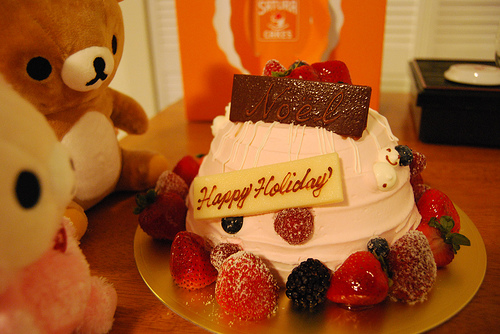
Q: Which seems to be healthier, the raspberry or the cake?
A: The raspberry is healthier than the cake.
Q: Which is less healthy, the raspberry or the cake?
A: The cake is less healthy than the raspberry.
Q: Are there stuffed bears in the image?
A: Yes, there is a stuffed bear.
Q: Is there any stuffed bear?
A: Yes, there is a stuffed bear.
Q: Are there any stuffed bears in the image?
A: Yes, there is a stuffed bear.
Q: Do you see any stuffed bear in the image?
A: Yes, there is a stuffed bear.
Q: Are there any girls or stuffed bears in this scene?
A: Yes, there is a stuffed bear.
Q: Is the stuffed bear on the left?
A: Yes, the stuffed bear is on the left of the image.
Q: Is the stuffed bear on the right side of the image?
A: No, the stuffed bear is on the left of the image.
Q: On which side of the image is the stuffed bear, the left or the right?
A: The stuffed bear is on the left of the image.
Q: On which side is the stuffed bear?
A: The stuffed bear is on the left of the image.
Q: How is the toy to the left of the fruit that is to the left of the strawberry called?
A: The toy is a stuffed bear.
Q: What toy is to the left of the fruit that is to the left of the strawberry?
A: The toy is a stuffed bear.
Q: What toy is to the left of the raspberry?
A: The toy is a stuffed bear.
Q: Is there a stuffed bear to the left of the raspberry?
A: Yes, there is a stuffed bear to the left of the raspberry.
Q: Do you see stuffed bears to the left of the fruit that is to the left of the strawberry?
A: Yes, there is a stuffed bear to the left of the raspberry.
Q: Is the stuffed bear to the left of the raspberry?
A: Yes, the stuffed bear is to the left of the raspberry.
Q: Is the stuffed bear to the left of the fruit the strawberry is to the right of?
A: Yes, the stuffed bear is to the left of the raspberry.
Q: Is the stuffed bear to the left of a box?
A: Yes, the stuffed bear is to the left of a box.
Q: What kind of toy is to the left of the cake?
A: The toy is a stuffed bear.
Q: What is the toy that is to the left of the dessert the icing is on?
A: The toy is a stuffed bear.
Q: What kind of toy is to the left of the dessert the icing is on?
A: The toy is a stuffed bear.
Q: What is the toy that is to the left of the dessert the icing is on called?
A: The toy is a stuffed bear.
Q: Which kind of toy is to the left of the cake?
A: The toy is a stuffed bear.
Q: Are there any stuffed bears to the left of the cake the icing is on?
A: Yes, there is a stuffed bear to the left of the cake.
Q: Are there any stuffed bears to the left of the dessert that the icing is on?
A: Yes, there is a stuffed bear to the left of the cake.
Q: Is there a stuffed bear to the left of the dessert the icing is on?
A: Yes, there is a stuffed bear to the left of the cake.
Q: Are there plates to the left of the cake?
A: No, there is a stuffed bear to the left of the cake.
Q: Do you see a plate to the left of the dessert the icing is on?
A: No, there is a stuffed bear to the left of the cake.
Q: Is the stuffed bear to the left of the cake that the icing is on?
A: Yes, the stuffed bear is to the left of the cake.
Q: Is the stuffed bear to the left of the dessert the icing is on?
A: Yes, the stuffed bear is to the left of the cake.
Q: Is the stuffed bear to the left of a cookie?
A: No, the stuffed bear is to the left of the cake.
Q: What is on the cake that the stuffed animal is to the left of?
A: The icing is on the cake.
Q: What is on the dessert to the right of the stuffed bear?
A: The icing is on the cake.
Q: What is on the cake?
A: The icing is on the cake.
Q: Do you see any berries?
A: Yes, there are berries.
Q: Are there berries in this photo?
A: Yes, there are berries.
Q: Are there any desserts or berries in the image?
A: Yes, there are berries.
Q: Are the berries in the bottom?
A: Yes, the berries are in the bottom of the image.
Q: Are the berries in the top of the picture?
A: No, the berries are in the bottom of the image.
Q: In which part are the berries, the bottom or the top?
A: The berries are in the bottom of the image.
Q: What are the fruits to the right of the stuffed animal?
A: The fruits are berries.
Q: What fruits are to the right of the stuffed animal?
A: The fruits are berries.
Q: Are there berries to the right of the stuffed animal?
A: Yes, there are berries to the right of the stuffed animal.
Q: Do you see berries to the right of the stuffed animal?
A: Yes, there are berries to the right of the stuffed animal.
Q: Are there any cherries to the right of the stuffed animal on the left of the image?
A: No, there are berries to the right of the stuffed animal.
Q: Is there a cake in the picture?
A: Yes, there is a cake.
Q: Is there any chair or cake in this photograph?
A: Yes, there is a cake.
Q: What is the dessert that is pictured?
A: The dessert is a cake.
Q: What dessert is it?
A: The dessert is a cake.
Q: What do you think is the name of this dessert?
A: This is a cake.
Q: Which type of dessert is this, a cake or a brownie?
A: This is a cake.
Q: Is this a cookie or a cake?
A: This is a cake.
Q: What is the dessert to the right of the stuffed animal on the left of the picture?
A: The dessert is a cake.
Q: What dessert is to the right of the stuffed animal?
A: The dessert is a cake.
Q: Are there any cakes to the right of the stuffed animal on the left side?
A: Yes, there is a cake to the right of the stuffed animal.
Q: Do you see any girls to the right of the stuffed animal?
A: No, there is a cake to the right of the stuffed animal.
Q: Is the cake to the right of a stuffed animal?
A: Yes, the cake is to the right of a stuffed animal.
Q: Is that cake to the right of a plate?
A: No, the cake is to the right of a stuffed animal.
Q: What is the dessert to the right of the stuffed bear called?
A: The dessert is a cake.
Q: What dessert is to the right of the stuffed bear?
A: The dessert is a cake.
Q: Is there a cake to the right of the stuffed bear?
A: Yes, there is a cake to the right of the stuffed bear.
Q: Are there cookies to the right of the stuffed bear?
A: No, there is a cake to the right of the stuffed bear.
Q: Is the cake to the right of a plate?
A: No, the cake is to the right of the stuffed bear.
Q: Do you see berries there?
A: Yes, there are berries.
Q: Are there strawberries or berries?
A: Yes, there are berries.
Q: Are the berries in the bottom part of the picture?
A: Yes, the berries are in the bottom of the image.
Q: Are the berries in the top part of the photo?
A: No, the berries are in the bottom of the image.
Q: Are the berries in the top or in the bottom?
A: The berries are in the bottom of the image.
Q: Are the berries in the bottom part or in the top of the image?
A: The berries are in the bottom of the image.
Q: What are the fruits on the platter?
A: The fruits are berries.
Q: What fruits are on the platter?
A: The fruits are berries.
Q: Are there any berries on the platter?
A: Yes, there are berries on the platter.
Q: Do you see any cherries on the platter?
A: No, there are berries on the platter.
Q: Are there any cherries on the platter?
A: No, there are berries on the platter.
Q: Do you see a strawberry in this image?
A: Yes, there is a strawberry.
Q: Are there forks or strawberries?
A: Yes, there is a strawberry.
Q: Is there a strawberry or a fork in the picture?
A: Yes, there is a strawberry.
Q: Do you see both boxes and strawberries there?
A: Yes, there are both a strawberry and a box.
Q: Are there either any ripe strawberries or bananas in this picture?
A: Yes, there is a ripe strawberry.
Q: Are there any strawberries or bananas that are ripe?
A: Yes, the strawberry is ripe.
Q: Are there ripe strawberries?
A: Yes, there is a ripe strawberry.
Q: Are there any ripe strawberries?
A: Yes, there is a ripe strawberry.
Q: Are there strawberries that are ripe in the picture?
A: Yes, there is a ripe strawberry.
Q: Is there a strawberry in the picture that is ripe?
A: Yes, there is a strawberry that is ripe.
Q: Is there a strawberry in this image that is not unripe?
A: Yes, there is an ripe strawberry.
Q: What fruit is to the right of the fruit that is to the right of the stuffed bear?
A: The fruit is a strawberry.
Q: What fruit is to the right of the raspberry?
A: The fruit is a strawberry.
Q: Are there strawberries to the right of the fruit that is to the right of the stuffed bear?
A: Yes, there is a strawberry to the right of the raspberry.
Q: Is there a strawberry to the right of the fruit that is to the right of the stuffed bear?
A: Yes, there is a strawberry to the right of the raspberry.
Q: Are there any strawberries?
A: Yes, there is a strawberry.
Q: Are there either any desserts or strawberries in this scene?
A: Yes, there is a strawberry.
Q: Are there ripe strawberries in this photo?
A: Yes, there is a ripe strawberry.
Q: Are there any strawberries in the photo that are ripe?
A: Yes, there is a strawberry that is ripe.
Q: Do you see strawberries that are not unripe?
A: Yes, there is an ripe strawberry.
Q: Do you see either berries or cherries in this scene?
A: Yes, there are berries.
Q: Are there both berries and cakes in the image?
A: Yes, there are both berries and a cake.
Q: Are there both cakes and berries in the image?
A: Yes, there are both berries and a cake.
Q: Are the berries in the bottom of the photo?
A: Yes, the berries are in the bottom of the image.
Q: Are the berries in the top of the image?
A: No, the berries are in the bottom of the image.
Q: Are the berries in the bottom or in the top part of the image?
A: The berries are in the bottom of the image.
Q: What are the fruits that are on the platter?
A: The fruits are berries.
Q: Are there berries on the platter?
A: Yes, there are berries on the platter.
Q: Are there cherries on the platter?
A: No, there are berries on the platter.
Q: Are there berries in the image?
A: Yes, there are berries.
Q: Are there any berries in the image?
A: Yes, there are berries.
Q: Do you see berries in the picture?
A: Yes, there are berries.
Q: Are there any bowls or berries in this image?
A: Yes, there are berries.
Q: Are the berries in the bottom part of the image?
A: Yes, the berries are in the bottom of the image.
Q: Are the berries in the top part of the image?
A: No, the berries are in the bottom of the image.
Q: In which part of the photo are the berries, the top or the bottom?
A: The berries are in the bottom of the image.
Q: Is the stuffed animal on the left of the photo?
A: Yes, the stuffed animal is on the left of the image.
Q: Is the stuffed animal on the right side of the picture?
A: No, the stuffed animal is on the left of the image.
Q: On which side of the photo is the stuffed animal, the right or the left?
A: The stuffed animal is on the left of the image.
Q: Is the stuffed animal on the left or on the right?
A: The stuffed animal is on the left of the image.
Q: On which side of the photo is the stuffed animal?
A: The stuffed animal is on the left of the image.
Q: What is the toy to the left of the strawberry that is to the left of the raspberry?
A: The toy is a stuffed animal.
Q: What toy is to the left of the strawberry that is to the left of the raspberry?
A: The toy is a stuffed animal.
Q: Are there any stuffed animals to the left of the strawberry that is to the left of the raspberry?
A: Yes, there is a stuffed animal to the left of the strawberry.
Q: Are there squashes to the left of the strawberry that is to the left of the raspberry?
A: No, there is a stuffed animal to the left of the strawberry.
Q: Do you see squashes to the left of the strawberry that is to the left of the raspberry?
A: No, there is a stuffed animal to the left of the strawberry.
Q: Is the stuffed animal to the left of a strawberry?
A: Yes, the stuffed animal is to the left of a strawberry.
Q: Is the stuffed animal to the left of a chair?
A: No, the stuffed animal is to the left of a strawberry.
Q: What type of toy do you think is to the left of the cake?
A: The toy is a stuffed animal.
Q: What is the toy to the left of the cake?
A: The toy is a stuffed animal.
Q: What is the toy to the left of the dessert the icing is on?
A: The toy is a stuffed animal.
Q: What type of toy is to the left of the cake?
A: The toy is a stuffed animal.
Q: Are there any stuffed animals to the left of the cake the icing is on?
A: Yes, there is a stuffed animal to the left of the cake.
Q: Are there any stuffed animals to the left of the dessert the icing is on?
A: Yes, there is a stuffed animal to the left of the cake.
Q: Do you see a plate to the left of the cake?
A: No, there is a stuffed animal to the left of the cake.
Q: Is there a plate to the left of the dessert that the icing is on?
A: No, there is a stuffed animal to the left of the cake.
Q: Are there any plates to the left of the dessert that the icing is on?
A: No, there is a stuffed animal to the left of the cake.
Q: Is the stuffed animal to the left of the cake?
A: Yes, the stuffed animal is to the left of the cake.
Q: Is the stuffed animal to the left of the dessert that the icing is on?
A: Yes, the stuffed animal is to the left of the cake.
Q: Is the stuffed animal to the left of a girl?
A: No, the stuffed animal is to the left of the cake.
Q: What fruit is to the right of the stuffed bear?
A: The fruit is a raspberry.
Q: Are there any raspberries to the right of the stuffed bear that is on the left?
A: Yes, there is a raspberry to the right of the stuffed bear.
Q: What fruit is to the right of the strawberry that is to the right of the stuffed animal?
A: The fruit is a raspberry.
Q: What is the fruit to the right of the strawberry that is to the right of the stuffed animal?
A: The fruit is a raspberry.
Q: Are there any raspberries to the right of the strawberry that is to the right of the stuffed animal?
A: Yes, there is a raspberry to the right of the strawberry.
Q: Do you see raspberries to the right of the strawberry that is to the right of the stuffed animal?
A: Yes, there is a raspberry to the right of the strawberry.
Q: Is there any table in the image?
A: Yes, there is a table.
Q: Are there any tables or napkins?
A: Yes, there is a table.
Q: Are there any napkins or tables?
A: Yes, there is a table.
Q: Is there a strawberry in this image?
A: Yes, there is a strawberry.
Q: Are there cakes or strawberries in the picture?
A: Yes, there is a strawberry.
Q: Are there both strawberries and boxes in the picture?
A: Yes, there are both a strawberry and a box.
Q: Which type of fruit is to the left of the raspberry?
A: The fruit is a strawberry.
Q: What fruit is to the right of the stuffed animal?
A: The fruit is a strawberry.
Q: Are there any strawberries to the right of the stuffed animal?
A: Yes, there is a strawberry to the right of the stuffed animal.